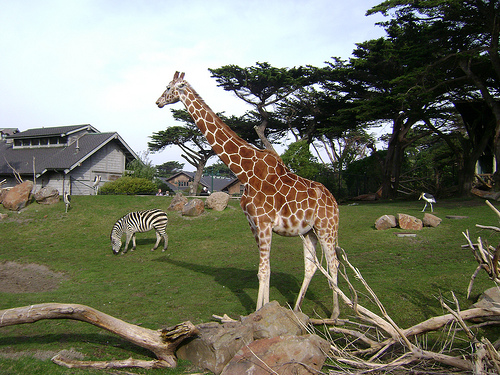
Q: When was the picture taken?
A: Daytime.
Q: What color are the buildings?
A: Gray and brown.